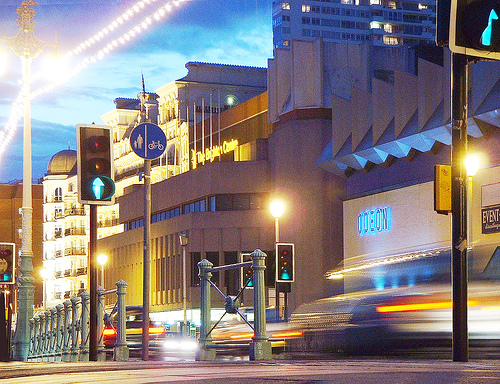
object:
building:
[271, 0, 440, 55]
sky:
[0, 0, 274, 184]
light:
[278, 270, 293, 282]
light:
[246, 277, 254, 288]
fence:
[195, 248, 272, 366]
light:
[87, 174, 116, 201]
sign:
[355, 205, 393, 236]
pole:
[451, 52, 469, 363]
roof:
[44, 147, 80, 175]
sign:
[127, 121, 167, 161]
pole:
[139, 159, 150, 362]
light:
[0, 272, 15, 283]